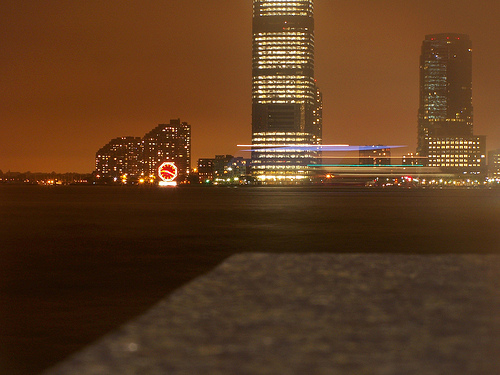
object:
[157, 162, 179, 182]
clock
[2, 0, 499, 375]
city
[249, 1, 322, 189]
building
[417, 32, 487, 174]
building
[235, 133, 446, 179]
light streaks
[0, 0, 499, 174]
sky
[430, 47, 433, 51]
lights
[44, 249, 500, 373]
slab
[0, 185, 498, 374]
water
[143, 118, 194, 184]
building